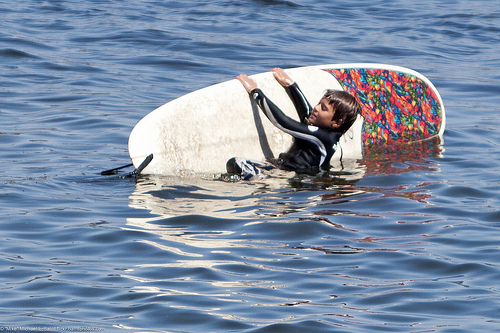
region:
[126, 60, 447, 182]
boy with surf board in th water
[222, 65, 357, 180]
boy wearing wet suit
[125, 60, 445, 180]
white and multi-colored surf board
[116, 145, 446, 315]
reflection of surf board in the water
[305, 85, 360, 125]
boy hair is brown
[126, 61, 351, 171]
white part of surf board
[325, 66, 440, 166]
brightly colored part of surf board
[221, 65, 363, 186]
boy holding on tightly to board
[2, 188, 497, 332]
water is deep blue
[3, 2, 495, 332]
water is not very wavy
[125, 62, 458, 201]
a young boy holding on to a surf board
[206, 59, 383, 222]
a young boy in the water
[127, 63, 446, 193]
a white surf board with a design on it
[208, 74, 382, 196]
a young boy wearing a wet suit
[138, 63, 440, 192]
a surf board on its side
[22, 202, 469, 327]
a body of water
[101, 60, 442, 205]
a boy in the water with a surf board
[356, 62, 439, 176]
several different colors on a surf board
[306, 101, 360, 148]
a boy with wet hair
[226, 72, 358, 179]
a boy in a black and white wet suit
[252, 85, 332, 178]
A black and white surf wear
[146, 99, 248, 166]
A surf board in the water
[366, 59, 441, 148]
A multi-colored edge of a surf board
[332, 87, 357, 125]
Brown hair in the photo.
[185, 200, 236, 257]
Light reflections on the water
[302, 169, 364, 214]
Shadows in the water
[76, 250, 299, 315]
Waves in the water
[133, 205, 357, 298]
Blue sea waters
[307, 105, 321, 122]
A boy smiling on the photo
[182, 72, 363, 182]
A boy holding on the capsized surf board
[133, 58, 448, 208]
a boy hanging on to a surf board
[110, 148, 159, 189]
black fins of the surf board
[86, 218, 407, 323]
calm blue water of the ocean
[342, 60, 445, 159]
coloful pattern on the front of the surfboard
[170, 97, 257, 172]
white top of the surf board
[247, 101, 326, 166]
white stripe on the boy's wet suit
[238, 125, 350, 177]
the boy's blac wet suit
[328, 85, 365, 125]
the boy's wet brown hair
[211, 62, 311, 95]
the boy's hands holding on to the surfboard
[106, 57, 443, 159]
a surf board sideways in the ocean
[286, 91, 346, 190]
boy holding on to a surfboard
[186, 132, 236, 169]
surfboard is white and colorful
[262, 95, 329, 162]
kid wearing black swimwear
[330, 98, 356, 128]
kid with black hair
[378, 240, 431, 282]
medium ripples in water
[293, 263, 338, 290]
water is dark blue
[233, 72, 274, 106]
left hand on surfboard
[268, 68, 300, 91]
right hand on surfboard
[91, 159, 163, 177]
black cord on surfboard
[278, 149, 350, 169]
swim outfit is black and gray